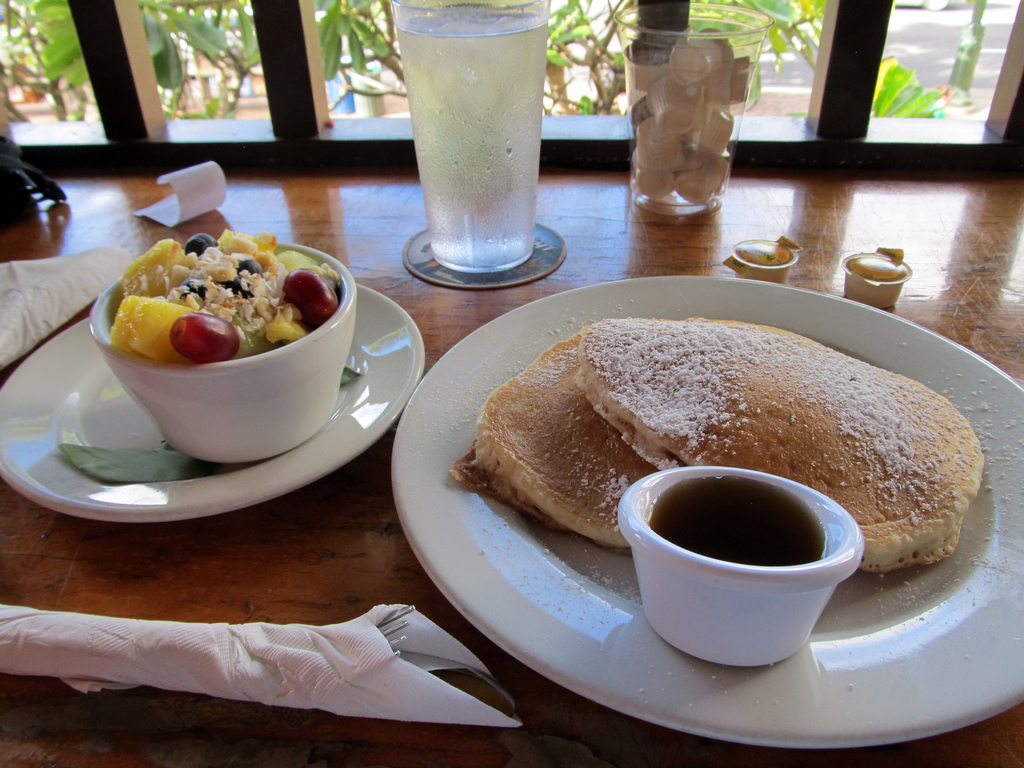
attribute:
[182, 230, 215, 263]
piece — food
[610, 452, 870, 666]
small/white cup — filled with syrup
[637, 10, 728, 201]
cup — plastic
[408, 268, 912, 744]
plate — white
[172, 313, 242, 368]
grape — red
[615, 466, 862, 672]
cup — white 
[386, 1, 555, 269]
glass — Tall 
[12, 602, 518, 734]
napkin — white 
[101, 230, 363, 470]
cup — white 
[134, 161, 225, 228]
wrapper — white 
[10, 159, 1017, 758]
table — wooden 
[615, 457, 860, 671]
container — Little , white 